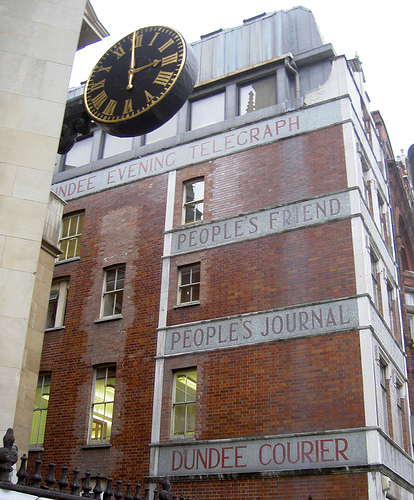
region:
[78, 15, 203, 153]
a clock with roman numerals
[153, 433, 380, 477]
writing on a wall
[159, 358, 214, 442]
window on a wall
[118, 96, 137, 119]
the roman numeral for 6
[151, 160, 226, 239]
relection on a window.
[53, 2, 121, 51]
overhang from the roof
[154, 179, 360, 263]
the words "people's friend"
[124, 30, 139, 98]
minute hand on a clock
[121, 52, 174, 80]
hour hand on a clock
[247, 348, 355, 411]
bricks of different shades of red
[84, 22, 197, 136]
clock is black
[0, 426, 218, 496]
pointy metal fence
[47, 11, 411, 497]
the building is tall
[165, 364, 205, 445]
window has four panes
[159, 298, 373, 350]
words say People's Journal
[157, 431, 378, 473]
words say Dundee Courier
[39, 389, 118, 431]
light is hanging from ceiling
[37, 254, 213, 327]
no light on in this room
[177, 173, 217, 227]
the window shows reflections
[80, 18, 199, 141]
it is 3 o'clock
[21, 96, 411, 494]
The building is brick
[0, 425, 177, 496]
The gate is black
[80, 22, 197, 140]
The clock is analog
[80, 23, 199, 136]
The clock face is black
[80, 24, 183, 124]
Clock numbers are gold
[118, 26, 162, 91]
Clock hands are gold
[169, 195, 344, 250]
Sign says peoples friend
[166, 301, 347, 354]
Sign says People's Journal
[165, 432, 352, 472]
Sign says Dundee Courier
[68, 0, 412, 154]
The sky is overcast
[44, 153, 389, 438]
A red brick building.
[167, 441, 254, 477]
The word DUNDEE in red lettering.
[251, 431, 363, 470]
The word COURIER in red lettering.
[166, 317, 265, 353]
The word PEOPLE'S on side of building.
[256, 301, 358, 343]
The word JOURNAL on side of building.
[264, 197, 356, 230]
The word FRIEND on side of building.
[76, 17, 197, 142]
A round clock with black face.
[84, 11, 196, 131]
A clock with gold roman numerals.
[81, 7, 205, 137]
The time on the clock is 3:00.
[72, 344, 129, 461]
A long window on side of building.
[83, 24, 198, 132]
The black and gold clock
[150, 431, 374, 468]
Dundee Courier in red letters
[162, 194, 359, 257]
Words People's Friend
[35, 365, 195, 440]
Three windows with light on inside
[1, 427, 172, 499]
The black balcony railing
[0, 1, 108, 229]
Gray left side of building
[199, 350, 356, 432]
Multicolored brick wall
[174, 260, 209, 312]
A single dark window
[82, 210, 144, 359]
Faded brick wall around dark window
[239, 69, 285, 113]
Shiny top window with reflection